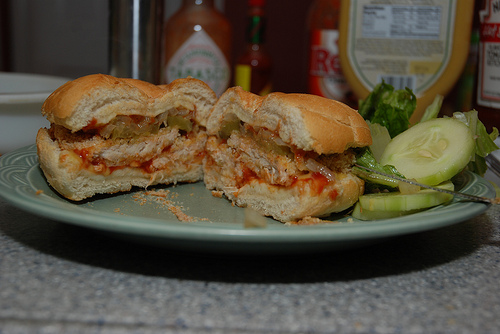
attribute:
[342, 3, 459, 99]
label — ingredients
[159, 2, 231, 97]
sauce — bottled, Tabasco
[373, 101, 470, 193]
cucumber — round, slicked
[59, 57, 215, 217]
sandwich — half, chicken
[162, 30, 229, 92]
label — white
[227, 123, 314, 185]
chicken — breaded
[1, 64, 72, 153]
bowl — white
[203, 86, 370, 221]
half sandwich — chicken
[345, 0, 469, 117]
bottle — mustard, upside down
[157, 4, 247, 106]
bottle — glass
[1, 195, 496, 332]
tabletop — grey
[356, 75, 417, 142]
green lettuce — dark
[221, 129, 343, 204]
sauce — red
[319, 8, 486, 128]
bottle — yellow, mustard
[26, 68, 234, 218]
half sandwich — chicken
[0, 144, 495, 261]
plate — gray, stoneware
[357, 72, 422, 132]
lettuce — green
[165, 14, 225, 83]
tabasco — sauce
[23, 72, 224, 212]
sandwich — half, chicken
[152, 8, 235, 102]
bottle — Frank's Red Hot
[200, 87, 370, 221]
sandwich — half, chicken